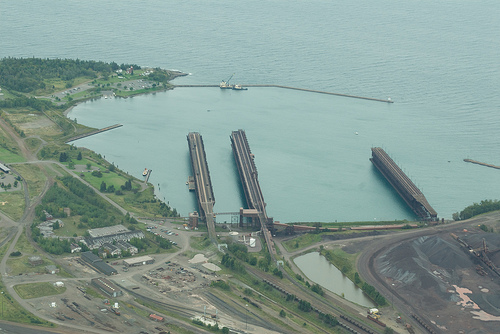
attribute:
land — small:
[2, 222, 496, 332]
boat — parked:
[218, 74, 251, 91]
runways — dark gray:
[164, 84, 285, 257]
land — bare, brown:
[24, 124, 73, 140]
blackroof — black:
[82, 252, 117, 278]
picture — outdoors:
[0, 2, 498, 331]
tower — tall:
[162, 203, 217, 246]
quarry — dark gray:
[373, 217, 498, 329]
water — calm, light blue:
[2, 1, 499, 222]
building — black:
[69, 244, 117, 294]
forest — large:
[1, 55, 159, 92]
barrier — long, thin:
[163, 79, 394, 107]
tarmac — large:
[356, 216, 497, 331]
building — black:
[73, 219, 131, 249]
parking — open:
[82, 222, 216, 311]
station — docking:
[360, 135, 454, 236]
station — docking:
[182, 126, 228, 226]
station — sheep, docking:
[222, 121, 276, 257]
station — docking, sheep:
[179, 80, 397, 116]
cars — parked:
[134, 223, 189, 263]